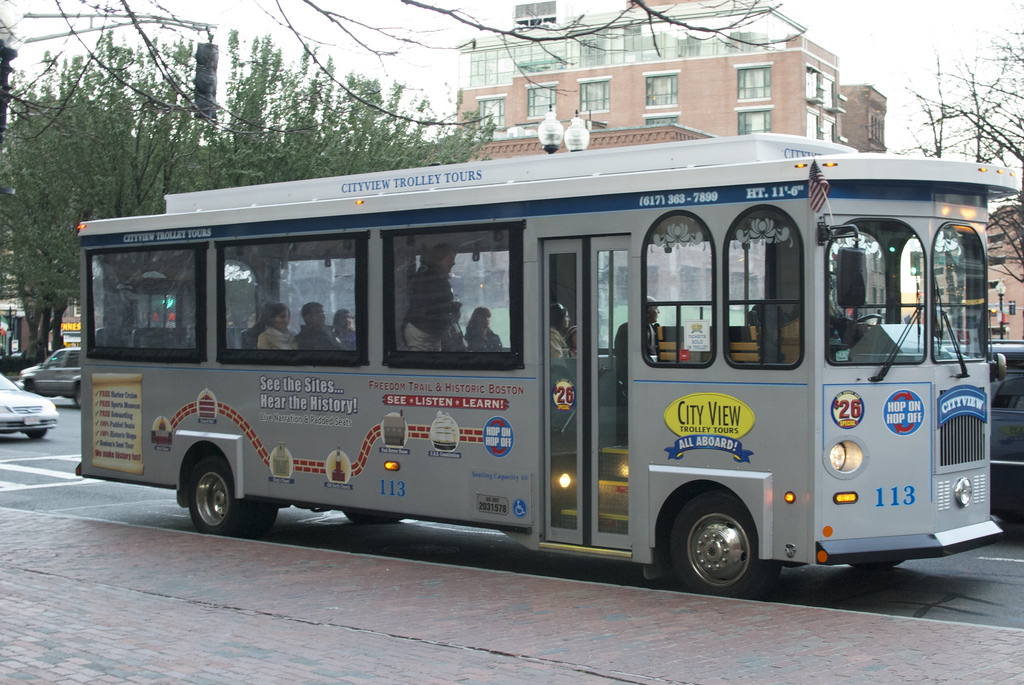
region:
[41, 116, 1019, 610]
the bus is gray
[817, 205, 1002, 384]
two windows on front the bus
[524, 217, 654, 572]
the front door of a bus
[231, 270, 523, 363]
people inside the bus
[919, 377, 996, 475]
the vent of a bus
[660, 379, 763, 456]
yellow sign on a bus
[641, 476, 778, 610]
front wheel of a bus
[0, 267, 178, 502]
cars behind the bus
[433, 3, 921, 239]
a building behind a bus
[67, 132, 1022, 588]
The silver trolley car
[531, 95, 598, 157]
The lights seen above the troller car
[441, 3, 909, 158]
The brick building shown above the trolley car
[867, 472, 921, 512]
Number written in blue on the front of the trolley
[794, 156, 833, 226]
The USA flag on the trolley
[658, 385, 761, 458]
The yellow oval on the side of the trolley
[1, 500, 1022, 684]
The brick sidewalk next to the trolley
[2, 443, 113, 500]
The crosswalk behind the trolley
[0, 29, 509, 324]
The green trees behind the trolley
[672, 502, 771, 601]
A front tire on a bus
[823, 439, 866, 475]
A headlight on a bus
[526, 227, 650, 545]
A door on a bus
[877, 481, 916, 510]
A blue number on a bus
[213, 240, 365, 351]
A window on a bus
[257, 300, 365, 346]
Passengers sitting in a bus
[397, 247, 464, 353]
A standing passenger in a bus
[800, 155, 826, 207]
A small flag on a bus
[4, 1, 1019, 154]
light in daytime sky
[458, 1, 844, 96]
building with glass rooftop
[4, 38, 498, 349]
green leaves of tree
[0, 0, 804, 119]
branches with no leaves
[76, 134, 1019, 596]
bus with trolley design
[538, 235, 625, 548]
double doors with windows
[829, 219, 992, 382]
wipers on top of windshields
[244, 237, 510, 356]
riders sitting in seats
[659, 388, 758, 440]
yellow sign with black letters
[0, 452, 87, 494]
white lines on asphalt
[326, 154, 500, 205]
CITYVIEW TROLLEY TOURS written on the trolley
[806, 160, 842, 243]
american flag on the trolley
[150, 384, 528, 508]
map on the side of the trolley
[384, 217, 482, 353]
person standing on the trolley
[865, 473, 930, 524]
113 written on the front of the trolley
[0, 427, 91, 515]
pedestrian crosswalk behind the trolley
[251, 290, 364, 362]
people sitting on the trolley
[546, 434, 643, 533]
lights on the steps of the trolley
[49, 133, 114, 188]
green leaves on the tree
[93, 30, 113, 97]
wave on the water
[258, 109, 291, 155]
wave on the water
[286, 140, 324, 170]
wave on the water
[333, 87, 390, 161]
wave on the water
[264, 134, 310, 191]
wave on the water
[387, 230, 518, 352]
glass is clear and clean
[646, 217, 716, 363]
glass is clear and clean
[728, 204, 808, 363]
glass is clear and clean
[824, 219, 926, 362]
glass is clear and clean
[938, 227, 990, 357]
glass is clear and clean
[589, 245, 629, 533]
glass is clear and clean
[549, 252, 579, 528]
glass is clear and clean